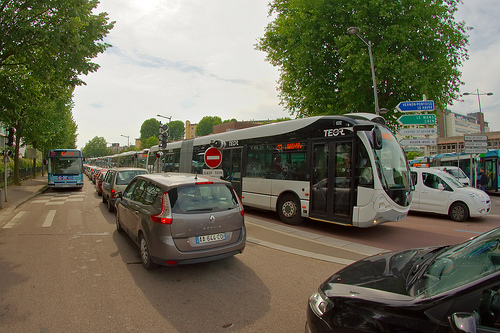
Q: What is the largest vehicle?
A: Bus.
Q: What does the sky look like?
A: Cloudy.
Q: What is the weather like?
A: Cloudy.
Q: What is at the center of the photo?
A: A grey hatchback with its brake lights on.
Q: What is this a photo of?
A: Traffic in a small city.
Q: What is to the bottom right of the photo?
A: Black car.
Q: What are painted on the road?
A: White lines.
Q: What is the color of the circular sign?
A: Red and White.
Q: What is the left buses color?
A: Blue.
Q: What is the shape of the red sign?
A: Circle.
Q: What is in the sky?
A: Clouds.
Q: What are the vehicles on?
A: Road.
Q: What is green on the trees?
A: Leaves.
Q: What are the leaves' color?
A: Green.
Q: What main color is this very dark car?
A: Black.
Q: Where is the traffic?
A: On the road.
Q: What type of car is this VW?
A: Volkswagon.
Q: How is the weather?
A: Clear.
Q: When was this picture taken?
A: Daytime.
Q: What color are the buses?
A: White and blue.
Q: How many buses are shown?
A: Two.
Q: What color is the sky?
A: Blue.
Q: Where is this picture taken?
A: A street.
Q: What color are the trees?
A: Green.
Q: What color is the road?
A: Grey.